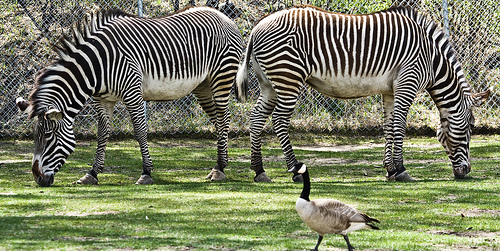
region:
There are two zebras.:
[16, 7, 495, 190]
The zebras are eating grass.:
[10, 9, 498, 179]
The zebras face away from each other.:
[12, 9, 487, 197]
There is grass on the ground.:
[3, 179, 288, 241]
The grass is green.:
[2, 183, 284, 248]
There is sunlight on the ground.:
[1, 185, 286, 247]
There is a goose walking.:
[281, 155, 387, 247]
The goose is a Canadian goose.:
[280, 159, 384, 249]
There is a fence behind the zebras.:
[0, 1, 498, 141]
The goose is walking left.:
[279, 156, 381, 249]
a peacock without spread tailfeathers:
[282, 159, 382, 246]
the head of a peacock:
[285, 159, 308, 178]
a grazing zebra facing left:
[16, 2, 245, 184]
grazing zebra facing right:
[237, 5, 481, 180]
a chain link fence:
[448, 2, 498, 47]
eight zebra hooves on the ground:
[75, 170, 425, 185]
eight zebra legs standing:
[75, 96, 417, 190]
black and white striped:
[145, 17, 197, 77]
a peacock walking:
[277, 157, 381, 249]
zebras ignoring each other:
[25, 7, 477, 178]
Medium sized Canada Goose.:
[255, 147, 382, 249]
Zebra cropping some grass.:
[15, 1, 254, 191]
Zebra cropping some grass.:
[222, 0, 487, 197]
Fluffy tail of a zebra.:
[227, 23, 263, 110]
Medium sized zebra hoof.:
[69, 163, 109, 190]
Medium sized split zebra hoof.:
[198, 161, 235, 186]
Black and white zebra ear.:
[461, 80, 497, 113]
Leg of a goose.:
[306, 224, 328, 249]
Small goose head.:
[282, 156, 315, 183]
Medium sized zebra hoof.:
[127, 161, 160, 191]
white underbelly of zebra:
[306, 65, 398, 108]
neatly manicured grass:
[12, 187, 259, 246]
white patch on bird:
[295, 162, 310, 177]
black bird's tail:
[358, 204, 401, 233]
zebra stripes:
[239, 19, 484, 177]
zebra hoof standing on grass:
[75, 170, 107, 185]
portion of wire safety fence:
[10, 8, 50, 79]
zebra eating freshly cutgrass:
[431, 100, 496, 190]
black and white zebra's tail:
[232, 35, 267, 121]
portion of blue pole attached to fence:
[438, 1, 450, 30]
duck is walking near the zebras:
[286, 157, 388, 249]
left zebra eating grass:
[9, 92, 77, 187]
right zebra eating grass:
[435, 84, 485, 185]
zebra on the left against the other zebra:
[11, 4, 246, 196]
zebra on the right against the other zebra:
[235, 3, 476, 193]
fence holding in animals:
[1, 1, 499, 136]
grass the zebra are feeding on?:
[2, 135, 499, 247]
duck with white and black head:
[288, 160, 310, 183]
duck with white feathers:
[294, 188, 366, 236]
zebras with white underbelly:
[308, 63, 398, 116]